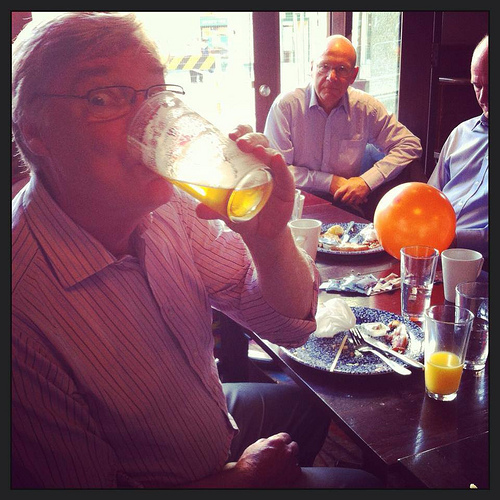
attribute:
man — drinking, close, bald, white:
[7, 16, 319, 499]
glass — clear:
[124, 94, 275, 227]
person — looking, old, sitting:
[265, 19, 422, 201]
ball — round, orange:
[365, 180, 467, 267]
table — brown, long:
[175, 172, 493, 484]